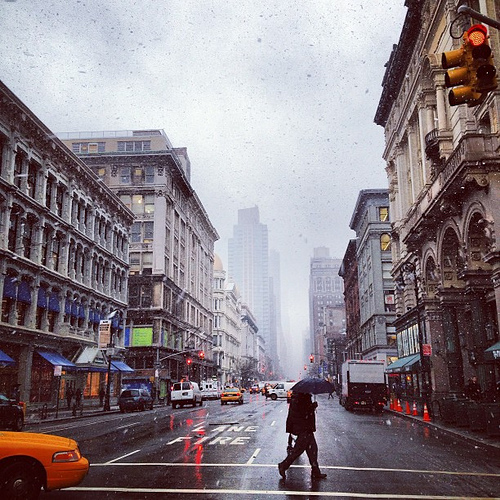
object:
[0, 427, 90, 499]
taxi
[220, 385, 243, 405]
taxi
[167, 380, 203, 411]
van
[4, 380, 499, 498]
street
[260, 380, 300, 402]
van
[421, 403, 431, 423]
cone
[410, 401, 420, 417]
cone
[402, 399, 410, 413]
cone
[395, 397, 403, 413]
cone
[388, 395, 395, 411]
cone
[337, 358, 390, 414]
box truck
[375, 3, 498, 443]
building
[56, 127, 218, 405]
building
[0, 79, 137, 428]
building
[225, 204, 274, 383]
building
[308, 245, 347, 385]
building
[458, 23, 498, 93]
stoplight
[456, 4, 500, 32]
pole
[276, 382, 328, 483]
person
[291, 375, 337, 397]
umbrella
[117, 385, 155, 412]
car